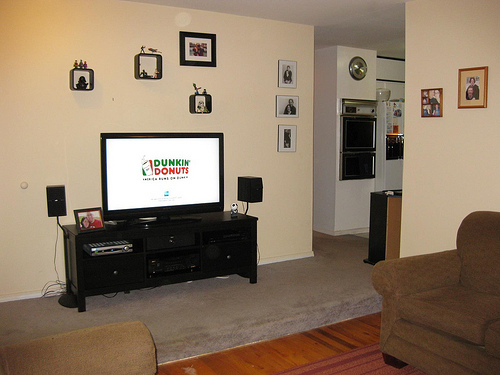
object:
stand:
[361, 188, 403, 267]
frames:
[275, 123, 297, 153]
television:
[97, 132, 225, 228]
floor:
[0, 230, 500, 375]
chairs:
[369, 210, 499, 375]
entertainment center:
[57, 210, 258, 311]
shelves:
[133, 53, 164, 80]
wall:
[0, 0, 313, 303]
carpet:
[0, 230, 380, 366]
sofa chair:
[0, 320, 157, 375]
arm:
[0, 318, 160, 375]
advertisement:
[139, 157, 191, 180]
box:
[82, 239, 134, 257]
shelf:
[144, 247, 203, 281]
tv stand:
[60, 210, 259, 313]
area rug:
[273, 342, 428, 375]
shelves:
[188, 93, 212, 114]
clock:
[347, 55, 368, 82]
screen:
[105, 138, 220, 213]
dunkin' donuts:
[153, 158, 191, 177]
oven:
[338, 98, 378, 182]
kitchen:
[308, 45, 403, 268]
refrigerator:
[374, 101, 403, 193]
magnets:
[392, 108, 402, 119]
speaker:
[46, 184, 67, 218]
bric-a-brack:
[67, 60, 96, 92]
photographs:
[72, 207, 106, 236]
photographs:
[457, 65, 489, 108]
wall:
[398, 0, 500, 259]